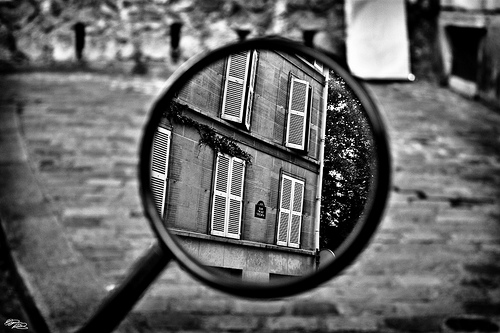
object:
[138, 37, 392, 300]
rear view mirror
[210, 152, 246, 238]
window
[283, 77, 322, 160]
window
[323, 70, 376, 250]
tree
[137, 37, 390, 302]
frame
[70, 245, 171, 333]
arm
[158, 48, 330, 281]
wall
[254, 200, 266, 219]
sign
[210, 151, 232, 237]
shutter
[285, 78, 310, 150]
shutter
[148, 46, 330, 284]
building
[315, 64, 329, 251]
gutter spout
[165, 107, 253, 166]
plant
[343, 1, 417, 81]
object